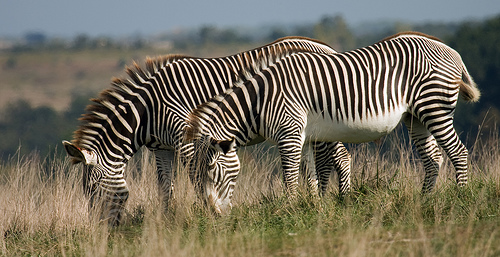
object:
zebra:
[184, 31, 481, 221]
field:
[6, 185, 500, 255]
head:
[178, 131, 243, 217]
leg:
[278, 126, 307, 207]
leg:
[406, 117, 443, 198]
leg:
[412, 102, 468, 193]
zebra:
[62, 36, 353, 226]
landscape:
[2, 0, 122, 130]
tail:
[458, 61, 480, 105]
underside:
[304, 105, 410, 144]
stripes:
[303, 46, 410, 113]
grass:
[359, 201, 494, 246]